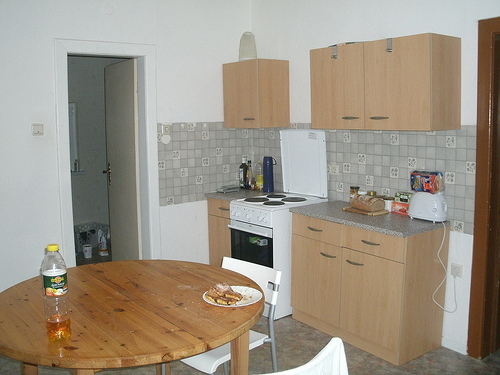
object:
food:
[205, 282, 244, 305]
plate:
[202, 285, 263, 308]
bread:
[350, 195, 385, 212]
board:
[342, 207, 389, 217]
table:
[0, 260, 265, 375]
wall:
[0, 0, 76, 295]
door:
[102, 59, 143, 262]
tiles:
[157, 122, 252, 205]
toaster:
[407, 191, 448, 223]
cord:
[432, 221, 461, 313]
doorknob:
[103, 162, 112, 186]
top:
[46, 243, 60, 252]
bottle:
[39, 242, 72, 341]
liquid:
[47, 316, 71, 337]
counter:
[345, 209, 448, 238]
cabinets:
[310, 33, 461, 131]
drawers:
[292, 212, 406, 264]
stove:
[227, 190, 328, 321]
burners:
[244, 195, 306, 206]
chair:
[180, 256, 282, 375]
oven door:
[228, 219, 274, 268]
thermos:
[263, 156, 277, 192]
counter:
[204, 183, 284, 201]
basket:
[74, 221, 109, 252]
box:
[249, 236, 269, 247]